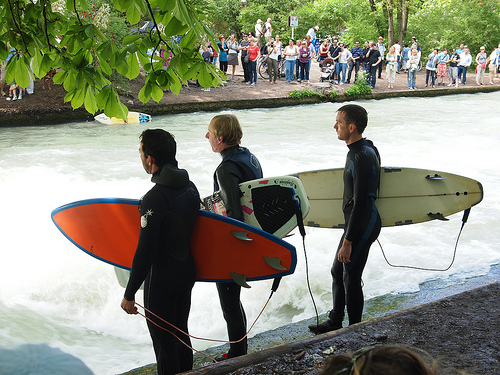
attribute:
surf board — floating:
[96, 112, 154, 129]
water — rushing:
[3, 90, 499, 375]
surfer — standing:
[308, 98, 388, 334]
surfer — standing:
[195, 111, 275, 362]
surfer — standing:
[128, 127, 207, 369]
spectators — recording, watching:
[195, 32, 487, 85]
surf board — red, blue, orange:
[53, 197, 299, 294]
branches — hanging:
[5, 4, 230, 112]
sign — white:
[286, 16, 299, 26]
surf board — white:
[286, 160, 490, 234]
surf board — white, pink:
[197, 179, 307, 251]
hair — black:
[141, 123, 183, 171]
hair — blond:
[209, 109, 241, 151]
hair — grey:
[336, 104, 369, 137]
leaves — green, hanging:
[55, 30, 131, 124]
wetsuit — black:
[329, 141, 383, 325]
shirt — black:
[364, 48, 379, 64]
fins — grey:
[228, 244, 282, 291]